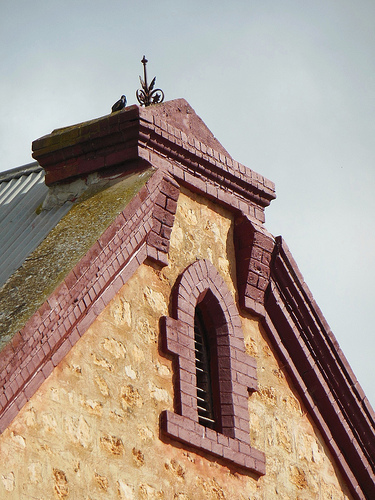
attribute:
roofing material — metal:
[1, 170, 57, 282]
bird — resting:
[100, 88, 135, 114]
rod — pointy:
[114, 61, 176, 97]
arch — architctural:
[164, 254, 245, 319]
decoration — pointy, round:
[130, 52, 176, 105]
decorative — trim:
[130, 45, 165, 107]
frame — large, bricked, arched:
[159, 257, 266, 476]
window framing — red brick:
[165, 254, 266, 479]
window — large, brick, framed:
[186, 290, 235, 433]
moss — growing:
[12, 175, 130, 272]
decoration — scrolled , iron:
[137, 57, 169, 113]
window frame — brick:
[150, 244, 271, 480]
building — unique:
[2, 94, 373, 499]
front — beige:
[120, 240, 248, 368]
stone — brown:
[73, 354, 159, 498]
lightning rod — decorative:
[134, 54, 165, 107]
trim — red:
[154, 313, 205, 429]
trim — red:
[42, 257, 117, 352]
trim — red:
[281, 319, 347, 397]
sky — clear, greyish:
[213, 10, 337, 158]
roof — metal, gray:
[1, 171, 92, 295]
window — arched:
[158, 248, 279, 471]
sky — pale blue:
[2, 2, 369, 406]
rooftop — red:
[29, 95, 276, 225]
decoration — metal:
[136, 54, 163, 107]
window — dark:
[186, 303, 229, 433]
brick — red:
[280, 286, 293, 298]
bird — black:
[104, 91, 126, 111]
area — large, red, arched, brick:
[158, 258, 267, 476]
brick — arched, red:
[158, 257, 267, 478]